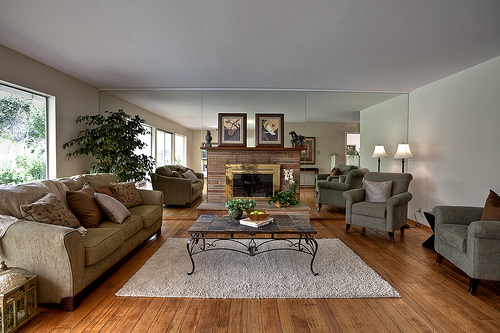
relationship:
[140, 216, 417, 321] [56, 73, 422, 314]
rug middle of room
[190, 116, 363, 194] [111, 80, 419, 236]
wall with mirrors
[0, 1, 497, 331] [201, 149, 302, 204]
room has a very big fireplace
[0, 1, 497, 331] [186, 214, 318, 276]
room has a table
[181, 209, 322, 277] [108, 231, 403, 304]
table sitting on a rug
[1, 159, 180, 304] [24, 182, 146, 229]
sofa has many pillows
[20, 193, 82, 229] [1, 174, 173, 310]
pillow on a sofa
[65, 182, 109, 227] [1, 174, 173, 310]
pillow on a sofa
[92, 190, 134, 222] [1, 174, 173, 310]
pillow on a sofa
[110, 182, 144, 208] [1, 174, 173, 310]
pillow on a sofa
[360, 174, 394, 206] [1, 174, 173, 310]
pillow on a sofa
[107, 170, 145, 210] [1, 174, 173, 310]
pillow on a sofa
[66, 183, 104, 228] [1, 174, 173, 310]
pillow on a sofa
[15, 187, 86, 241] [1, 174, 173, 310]
pillow on a sofa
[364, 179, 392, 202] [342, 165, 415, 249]
pillow on a chair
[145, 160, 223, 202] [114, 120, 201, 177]
sofa by a window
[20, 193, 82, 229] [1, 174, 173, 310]
pillow on sofa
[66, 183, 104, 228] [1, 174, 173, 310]
pillow on sofa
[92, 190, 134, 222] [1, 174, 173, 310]
pillow on sofa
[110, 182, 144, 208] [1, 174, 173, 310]
pillow on sofa